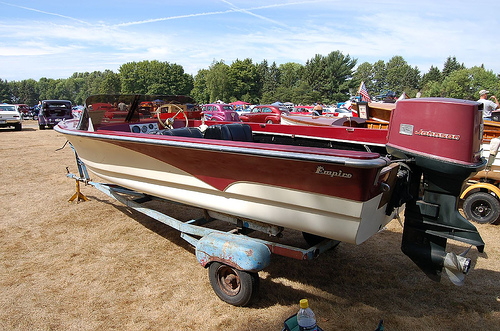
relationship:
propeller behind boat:
[443, 247, 475, 290] [49, 77, 497, 291]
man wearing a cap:
[475, 88, 499, 120] [477, 88, 490, 95]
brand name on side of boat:
[314, 165, 356, 182] [61, 83, 491, 312]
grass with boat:
[1, 122, 497, 329] [56, 61, 393, 326]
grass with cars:
[1, 122, 497, 329] [1, 93, 495, 131]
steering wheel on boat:
[157, 104, 188, 130] [61, 83, 491, 312]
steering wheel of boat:
[154, 102, 188, 132] [54, 89, 395, 245]